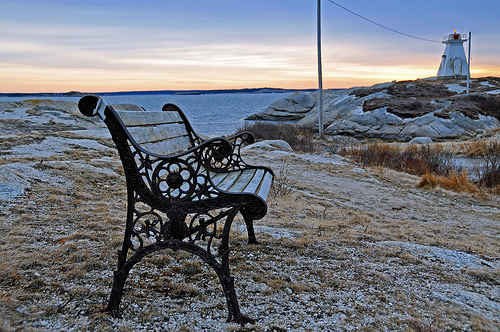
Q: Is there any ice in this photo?
A: Yes, there is ice.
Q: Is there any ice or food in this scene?
A: Yes, there is ice.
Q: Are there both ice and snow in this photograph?
A: Yes, there are both ice and snow.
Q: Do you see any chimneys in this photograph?
A: No, there are no chimneys.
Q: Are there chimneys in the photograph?
A: No, there are no chimneys.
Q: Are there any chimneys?
A: No, there are no chimneys.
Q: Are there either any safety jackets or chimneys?
A: No, there are no chimneys or safety jackets.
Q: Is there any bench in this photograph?
A: Yes, there is a bench.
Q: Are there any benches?
A: Yes, there is a bench.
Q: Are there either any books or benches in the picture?
A: Yes, there is a bench.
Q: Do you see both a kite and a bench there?
A: No, there is a bench but no kites.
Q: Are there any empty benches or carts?
A: Yes, there is an empty bench.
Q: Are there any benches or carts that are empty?
A: Yes, the bench is empty.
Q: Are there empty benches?
A: Yes, there is an empty bench.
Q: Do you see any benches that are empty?
A: Yes, there is a bench that is empty.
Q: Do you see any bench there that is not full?
A: Yes, there is a empty bench.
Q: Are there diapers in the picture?
A: No, there are no diapers.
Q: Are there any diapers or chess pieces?
A: No, there are no diapers or chess pieces.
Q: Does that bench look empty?
A: Yes, the bench is empty.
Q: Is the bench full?
A: No, the bench is empty.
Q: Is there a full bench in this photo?
A: No, there is a bench but it is empty.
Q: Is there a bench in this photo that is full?
A: No, there is a bench but it is empty.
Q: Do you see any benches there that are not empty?
A: No, there is a bench but it is empty.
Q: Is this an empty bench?
A: Yes, this is an empty bench.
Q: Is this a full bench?
A: No, this is an empty bench.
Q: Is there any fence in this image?
A: No, there are no fences.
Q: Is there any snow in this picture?
A: Yes, there is snow.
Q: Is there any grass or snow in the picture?
A: Yes, there is snow.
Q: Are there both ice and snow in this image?
A: Yes, there are both snow and ice.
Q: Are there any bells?
A: No, there are no bells.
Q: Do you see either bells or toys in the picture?
A: No, there are no bells or toys.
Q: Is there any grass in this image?
A: Yes, there is grass.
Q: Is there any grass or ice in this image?
A: Yes, there is grass.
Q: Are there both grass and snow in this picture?
A: Yes, there are both grass and snow.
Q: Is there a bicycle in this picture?
A: No, there are no bicycles.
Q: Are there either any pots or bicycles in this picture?
A: No, there are no bicycles or pots.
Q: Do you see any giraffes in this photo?
A: No, there are no giraffes.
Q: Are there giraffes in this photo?
A: No, there are no giraffes.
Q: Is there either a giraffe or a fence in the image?
A: No, there are no giraffes or fences.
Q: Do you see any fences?
A: No, there are no fences.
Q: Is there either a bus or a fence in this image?
A: No, there are no fences or buses.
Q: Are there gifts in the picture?
A: No, there are no gifts.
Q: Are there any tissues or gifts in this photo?
A: No, there are no gifts or tissues.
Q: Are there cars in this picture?
A: No, there are no cars.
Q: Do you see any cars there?
A: No, there are no cars.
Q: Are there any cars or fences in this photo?
A: No, there are no cars or fences.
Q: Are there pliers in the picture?
A: No, there are no pliers.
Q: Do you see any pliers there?
A: No, there are no pliers.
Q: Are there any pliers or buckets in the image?
A: No, there are no pliers or buckets.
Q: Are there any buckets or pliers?
A: No, there are no pliers or buckets.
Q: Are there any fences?
A: No, there are no fences.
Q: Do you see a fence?
A: No, there are no fences.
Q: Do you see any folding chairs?
A: No, there are no folding chairs.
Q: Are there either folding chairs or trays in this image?
A: No, there are no folding chairs or trays.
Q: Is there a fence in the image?
A: No, there are no fences.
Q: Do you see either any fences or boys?
A: No, there are no fences or boys.